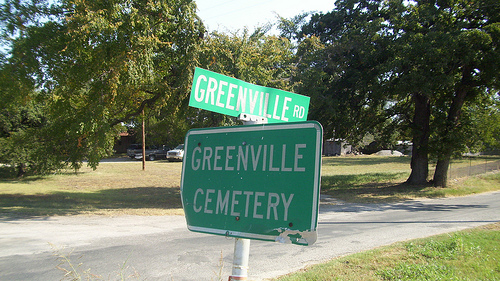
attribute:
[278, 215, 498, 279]
grassy —  field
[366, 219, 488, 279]
grass — green 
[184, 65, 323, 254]
boards — green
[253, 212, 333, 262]
ripped sign —  ripped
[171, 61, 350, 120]
sign — green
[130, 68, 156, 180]
poll —  wooden,  stick, pole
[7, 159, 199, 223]
field —  plain,  grassy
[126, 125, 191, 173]
cars — parked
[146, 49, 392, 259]
post — short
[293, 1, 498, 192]
tall tree —  tall, with stem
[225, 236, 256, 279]
post — white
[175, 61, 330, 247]
signs —   two 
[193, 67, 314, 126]
street sign —  street's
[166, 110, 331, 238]
sign — small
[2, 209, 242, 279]
road — clean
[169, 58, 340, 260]
text — white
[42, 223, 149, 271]
road — tarmacked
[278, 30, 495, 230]
trees — large 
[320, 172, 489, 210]
shadow — sunlight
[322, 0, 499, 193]
tree — big 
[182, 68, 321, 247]
post — green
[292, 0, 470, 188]
trees — leafy